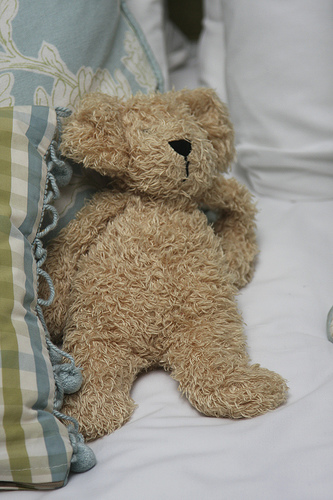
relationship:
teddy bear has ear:
[38, 87, 291, 444] [59, 87, 134, 177]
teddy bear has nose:
[38, 87, 291, 444] [171, 139, 193, 156]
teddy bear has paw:
[38, 87, 291, 444] [39, 294, 70, 332]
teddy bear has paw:
[38, 87, 291, 444] [218, 240, 255, 285]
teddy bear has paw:
[38, 87, 291, 444] [57, 385, 132, 435]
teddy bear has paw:
[38, 87, 291, 444] [185, 366, 292, 423]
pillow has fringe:
[3, 103, 86, 494] [30, 108, 93, 479]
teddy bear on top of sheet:
[38, 87, 291, 444] [55, 2, 331, 498]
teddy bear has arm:
[38, 87, 291, 444] [201, 183, 261, 258]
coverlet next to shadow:
[2, 2, 173, 133] [161, 2, 206, 73]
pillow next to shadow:
[194, 2, 332, 204] [161, 2, 206, 73]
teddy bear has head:
[38, 87, 291, 444] [70, 88, 239, 197]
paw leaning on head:
[218, 240, 255, 285] [70, 88, 239, 197]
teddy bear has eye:
[38, 87, 291, 444] [135, 126, 153, 139]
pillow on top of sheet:
[3, 103, 86, 494] [55, 2, 331, 498]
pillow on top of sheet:
[194, 2, 332, 204] [55, 2, 331, 498]